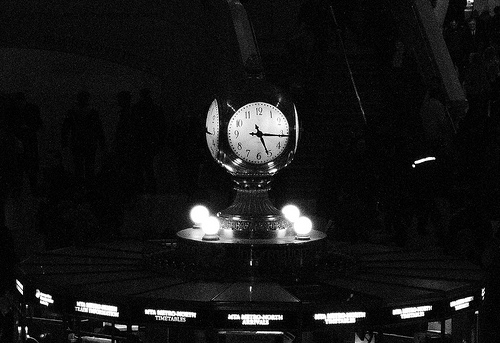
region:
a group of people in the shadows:
[1, 71, 176, 278]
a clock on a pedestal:
[206, 54, 311, 240]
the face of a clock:
[223, 94, 289, 163]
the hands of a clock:
[247, 121, 288, 158]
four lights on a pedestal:
[185, 201, 326, 252]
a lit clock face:
[226, 96, 293, 170]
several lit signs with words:
[14, 275, 492, 330]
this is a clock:
[186, 53, 328, 265]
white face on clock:
[228, 90, 291, 177]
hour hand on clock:
[248, 124, 290, 139]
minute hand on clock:
[250, 124, 270, 159]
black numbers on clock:
[229, 96, 289, 170]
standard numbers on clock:
[230, 102, 299, 171]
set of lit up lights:
[39, 270, 497, 342]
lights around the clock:
[185, 185, 334, 253]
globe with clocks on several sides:
[196, 75, 306, 185]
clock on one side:
[231, 100, 278, 155]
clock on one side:
[202, 108, 217, 145]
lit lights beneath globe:
[187, 195, 317, 240]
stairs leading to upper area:
[273, 14, 421, 213]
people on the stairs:
[373, 37, 413, 98]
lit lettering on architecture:
[379, 305, 441, 323]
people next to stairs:
[458, 19, 488, 67]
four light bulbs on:
[188, 204, 314, 241]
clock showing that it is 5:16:
[223, 99, 291, 163]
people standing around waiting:
[1, 83, 218, 240]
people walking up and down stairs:
[250, 2, 443, 197]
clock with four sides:
[202, 52, 302, 234]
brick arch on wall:
[5, 27, 167, 86]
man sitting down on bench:
[31, 149, 79, 220]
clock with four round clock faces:
[199, 52, 302, 234]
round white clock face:
[226, 101, 291, 163]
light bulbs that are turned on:
[187, 202, 316, 244]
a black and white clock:
[218, 88, 301, 182]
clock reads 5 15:
[216, 88, 303, 189]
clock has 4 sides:
[199, 86, 337, 181]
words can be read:
[64, 261, 455, 336]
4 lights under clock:
[188, 177, 314, 247]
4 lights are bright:
[183, 193, 324, 268]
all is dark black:
[11, 37, 139, 188]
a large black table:
[58, 186, 463, 331]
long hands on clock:
[235, 114, 314, 157]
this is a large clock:
[107, 73, 398, 333]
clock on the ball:
[230, 98, 285, 154]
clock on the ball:
[193, 97, 224, 149]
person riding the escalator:
[277, 20, 307, 65]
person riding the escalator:
[387, 31, 414, 83]